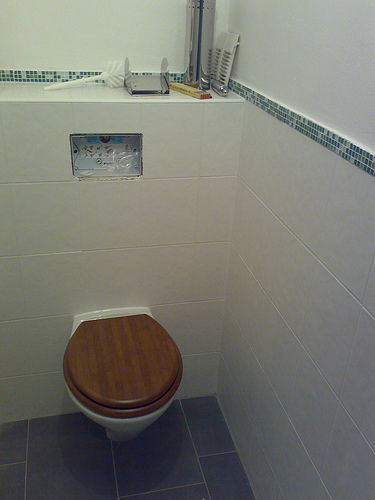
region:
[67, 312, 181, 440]
the toilet is white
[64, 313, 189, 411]
the toilet seat is wood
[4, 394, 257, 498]
the floor is blue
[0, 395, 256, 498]
the floor is tiled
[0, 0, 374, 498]
the wall is white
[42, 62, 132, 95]
the toilet brush is white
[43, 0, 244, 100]
the shelf has items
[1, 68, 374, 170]
the wall has a trim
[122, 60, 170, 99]
a metal object is on the shelf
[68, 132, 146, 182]
the wall has a hole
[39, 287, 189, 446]
toilet attached to wall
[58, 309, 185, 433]
brown wood looking toilet seat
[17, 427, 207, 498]
gray tile on floor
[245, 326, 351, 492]
off white tile on wall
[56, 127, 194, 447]
hole in wall above toilet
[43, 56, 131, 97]
white toilet brush on shelf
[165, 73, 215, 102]
some type of ruler on shelf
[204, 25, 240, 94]
plastic vent leaning up against wall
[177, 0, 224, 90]
metal container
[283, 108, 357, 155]
small glass tiles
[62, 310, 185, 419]
a wooden toilet seat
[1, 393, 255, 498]
a grey tiled floor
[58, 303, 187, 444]
a small toilet attached directly to the wall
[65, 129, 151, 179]
a hole in the wall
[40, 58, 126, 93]
a white toilet brush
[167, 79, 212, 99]
a box of yellow pencils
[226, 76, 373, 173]
a line of small green tiles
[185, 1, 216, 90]
a chrome toilet brush holder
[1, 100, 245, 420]
a wall of large white tiles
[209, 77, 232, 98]
a silver toilet paper roll holder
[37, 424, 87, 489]
Large floor tile to the left of the toilet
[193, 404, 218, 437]
Corner floor tile to the right of the toilet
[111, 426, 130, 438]
White base of the toilet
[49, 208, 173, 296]
White wall above the toilet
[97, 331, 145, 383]
Brown lid of the toilet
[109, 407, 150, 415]
Brown toilet seat below lid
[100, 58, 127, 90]
Bristles on the toilet brush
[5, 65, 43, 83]
Mosaic tile behind the shelf above the toilet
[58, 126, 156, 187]
Opening in the tile of the wall above the toilet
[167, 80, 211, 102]
Narrow yellow item on the shelf above the toilet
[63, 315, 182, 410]
the toilet seat is brown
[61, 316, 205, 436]
the toilet seat is closed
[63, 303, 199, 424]
the toilet seat is made of wood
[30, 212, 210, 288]
the wall is white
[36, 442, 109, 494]
the floor of blue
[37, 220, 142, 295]
the wall is tiled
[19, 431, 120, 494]
the floor is tiled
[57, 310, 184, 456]
toilet bowl is white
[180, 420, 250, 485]
the tile is rectangle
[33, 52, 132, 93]
toilet brush is on the counter